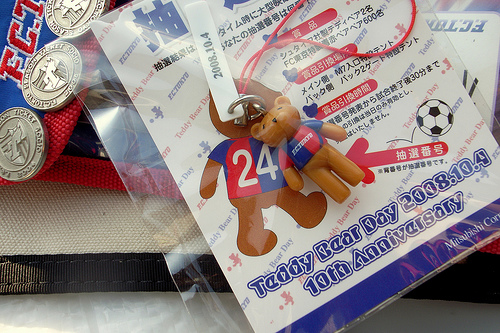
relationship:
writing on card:
[318, 58, 441, 140] [44, 0, 500, 314]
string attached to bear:
[236, 0, 418, 93] [243, 107, 371, 202]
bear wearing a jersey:
[243, 107, 371, 202] [277, 117, 324, 168]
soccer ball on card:
[416, 98, 452, 136] [90, 1, 498, 332]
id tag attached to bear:
[186, 4, 248, 125] [243, 107, 371, 202]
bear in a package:
[243, 107, 371, 202] [44, 0, 500, 314]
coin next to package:
[13, 42, 91, 111] [44, 0, 500, 314]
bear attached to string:
[243, 107, 371, 202] [236, 0, 418, 93]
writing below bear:
[243, 147, 495, 307] [243, 107, 371, 202]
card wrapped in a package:
[90, 1, 498, 332] [44, 0, 500, 314]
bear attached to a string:
[243, 107, 371, 202] [236, 0, 418, 93]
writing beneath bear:
[243, 147, 495, 307] [243, 107, 371, 202]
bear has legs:
[243, 107, 371, 202] [308, 159, 364, 200]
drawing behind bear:
[189, 82, 331, 258] [243, 107, 371, 202]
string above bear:
[236, 0, 418, 93] [243, 107, 371, 202]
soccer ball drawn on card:
[416, 98, 452, 136] [90, 1, 498, 332]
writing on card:
[243, 147, 495, 307] [90, 1, 498, 332]